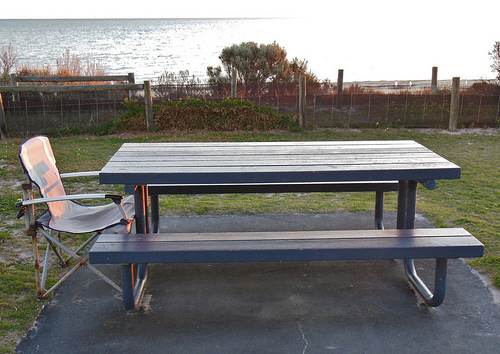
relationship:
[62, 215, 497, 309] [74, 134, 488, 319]
ground under bench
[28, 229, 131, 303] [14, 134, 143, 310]
legs of a chair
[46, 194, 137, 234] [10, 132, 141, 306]
seat of a chair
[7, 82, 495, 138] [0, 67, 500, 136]
fence with posts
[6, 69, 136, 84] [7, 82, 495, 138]
crossmember on a fence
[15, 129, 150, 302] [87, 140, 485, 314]
chair by a picnic table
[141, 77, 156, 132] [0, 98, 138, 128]
fence post for fence